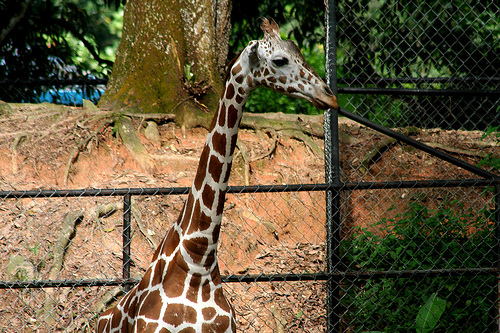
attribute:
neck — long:
[163, 78, 253, 273]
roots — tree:
[247, 112, 326, 153]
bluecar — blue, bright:
[22, 47, 104, 109]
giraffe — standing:
[50, 20, 450, 330]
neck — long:
[181, 75, 256, 265]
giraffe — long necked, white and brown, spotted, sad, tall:
[90, 19, 338, 328]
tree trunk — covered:
[109, 3, 240, 121]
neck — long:
[136, 82, 258, 287]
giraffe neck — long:
[153, 41, 278, 238]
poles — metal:
[2, 178, 495, 325]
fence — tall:
[331, 0, 498, 332]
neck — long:
[158, 63, 253, 265]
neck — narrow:
[154, 82, 249, 286]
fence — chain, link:
[332, 20, 499, 294]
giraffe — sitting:
[101, 22, 386, 319]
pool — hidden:
[5, 43, 106, 105]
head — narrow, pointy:
[243, 15, 339, 112]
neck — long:
[178, 68, 255, 252]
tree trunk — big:
[98, 0, 231, 110]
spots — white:
[134, 20, 177, 53]